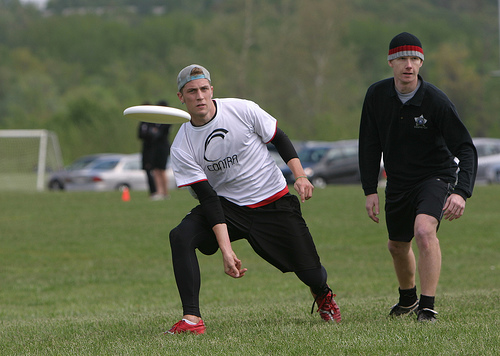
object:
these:
[24, 151, 498, 208]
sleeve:
[190, 179, 228, 226]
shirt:
[170, 98, 288, 207]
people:
[147, 97, 175, 199]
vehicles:
[280, 138, 384, 188]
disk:
[123, 105, 193, 125]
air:
[0, 0, 499, 355]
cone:
[121, 184, 129, 202]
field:
[0, 180, 499, 355]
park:
[1, 0, 499, 354]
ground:
[0, 186, 499, 354]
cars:
[65, 153, 179, 190]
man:
[355, 32, 480, 323]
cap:
[388, 32, 426, 60]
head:
[388, 41, 425, 80]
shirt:
[358, 74, 476, 201]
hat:
[177, 64, 213, 91]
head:
[175, 65, 214, 115]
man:
[164, 63, 342, 334]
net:
[1, 136, 37, 192]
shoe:
[163, 317, 205, 333]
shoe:
[311, 290, 346, 323]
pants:
[384, 173, 454, 242]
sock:
[419, 293, 434, 312]